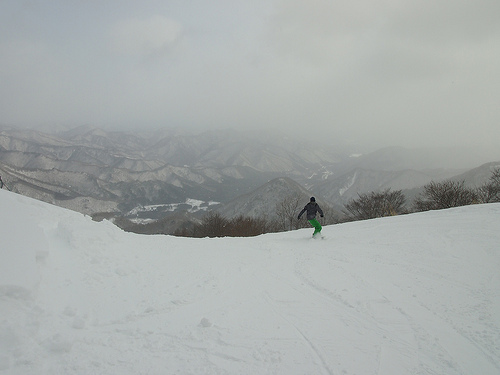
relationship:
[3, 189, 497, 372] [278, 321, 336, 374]
snow has tracks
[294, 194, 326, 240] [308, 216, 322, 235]
man in pants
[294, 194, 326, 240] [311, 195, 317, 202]
man wearing hat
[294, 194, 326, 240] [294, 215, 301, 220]
man wearing gloves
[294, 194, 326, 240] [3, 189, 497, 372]
man riding down snow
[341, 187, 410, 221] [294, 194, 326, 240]
trees in front of man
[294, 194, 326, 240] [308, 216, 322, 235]
man wearing pants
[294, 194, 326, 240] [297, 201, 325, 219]
man wearing jacket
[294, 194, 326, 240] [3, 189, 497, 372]
man going down snow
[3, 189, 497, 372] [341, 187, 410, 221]
snow has trees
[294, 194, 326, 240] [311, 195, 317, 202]
man has hat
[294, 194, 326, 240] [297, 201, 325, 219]
man has jacket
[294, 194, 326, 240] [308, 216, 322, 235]
man has pants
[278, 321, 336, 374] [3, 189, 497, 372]
tracks in snow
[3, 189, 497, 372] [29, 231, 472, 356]
snow on ground